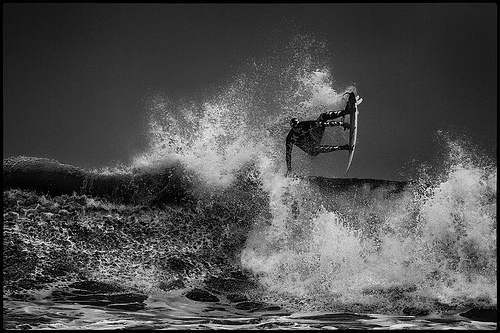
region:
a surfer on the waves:
[21, 14, 471, 319]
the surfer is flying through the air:
[238, 76, 378, 186]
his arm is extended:
[263, 125, 309, 195]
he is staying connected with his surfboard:
[331, 88, 373, 170]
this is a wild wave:
[158, 78, 390, 218]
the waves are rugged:
[266, 180, 496, 304]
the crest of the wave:
[12, 132, 155, 206]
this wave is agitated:
[34, 246, 266, 328]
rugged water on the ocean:
[27, 60, 476, 249]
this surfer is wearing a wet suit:
[256, 91, 373, 173]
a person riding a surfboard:
[269, 78, 367, 182]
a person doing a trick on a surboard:
[279, 85, 366, 194]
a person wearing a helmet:
[282, 115, 302, 129]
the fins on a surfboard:
[354, 93, 364, 104]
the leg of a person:
[322, 140, 346, 154]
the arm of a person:
[282, 145, 294, 167]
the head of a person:
[285, 110, 299, 127]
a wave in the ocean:
[17, 150, 205, 322]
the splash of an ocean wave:
[143, 64, 279, 156]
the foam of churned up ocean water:
[172, 285, 247, 320]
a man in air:
[263, 43, 437, 218]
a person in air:
[248, 66, 499, 231]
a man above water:
[248, 76, 423, 234]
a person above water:
[261, 70, 416, 229]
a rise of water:
[169, 33, 351, 229]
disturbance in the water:
[262, 218, 387, 295]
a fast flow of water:
[29, 139, 255, 261]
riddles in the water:
[116, 280, 214, 322]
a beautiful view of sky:
[92, 33, 202, 128]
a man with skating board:
[263, 95, 419, 202]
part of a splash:
[331, 255, 366, 285]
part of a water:
[238, 208, 270, 265]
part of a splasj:
[274, 195, 307, 252]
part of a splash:
[296, 245, 336, 320]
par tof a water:
[299, 254, 329, 309]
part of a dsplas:
[310, 230, 334, 273]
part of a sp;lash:
[328, 236, 365, 281]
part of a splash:
[285, 211, 310, 234]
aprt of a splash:
[261, 208, 305, 273]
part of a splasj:
[278, 268, 298, 310]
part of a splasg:
[293, 220, 319, 262]